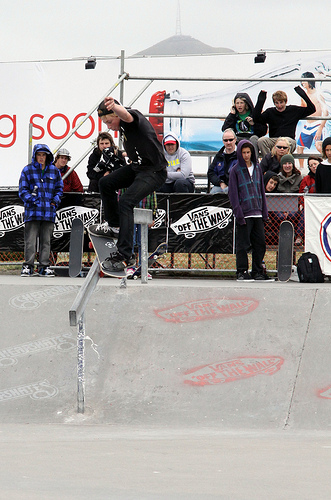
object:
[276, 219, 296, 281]
skateboard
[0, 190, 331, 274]
fence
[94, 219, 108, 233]
laces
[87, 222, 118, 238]
tennis shoe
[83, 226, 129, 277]
skateboard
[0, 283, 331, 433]
ramp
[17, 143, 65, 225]
plaid jacket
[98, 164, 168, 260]
pants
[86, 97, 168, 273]
man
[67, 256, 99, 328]
rail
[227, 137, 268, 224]
jacket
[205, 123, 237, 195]
person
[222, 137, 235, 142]
sunglasses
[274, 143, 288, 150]
sunglasses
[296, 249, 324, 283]
backpack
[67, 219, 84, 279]
skateboard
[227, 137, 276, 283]
guy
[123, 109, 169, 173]
shirt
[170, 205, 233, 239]
sign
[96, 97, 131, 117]
hat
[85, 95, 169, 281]
trick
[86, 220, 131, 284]
skateboarding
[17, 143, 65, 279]
guy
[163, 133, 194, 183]
sweater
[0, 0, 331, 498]
skateboard park